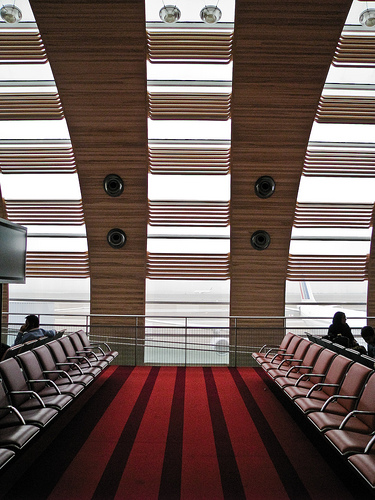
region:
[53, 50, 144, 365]
a large brown panel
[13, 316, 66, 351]
a man on a seat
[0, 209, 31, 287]
a TV over the man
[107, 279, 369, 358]
a plane out the window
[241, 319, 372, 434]
a row of empty chairs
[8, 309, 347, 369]
a fence behind the chairs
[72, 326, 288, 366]
a ramp behind the fence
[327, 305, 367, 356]
a woman on a chair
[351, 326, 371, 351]
a man bending over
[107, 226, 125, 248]
a brown circle on the panel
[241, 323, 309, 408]
chairs at the airport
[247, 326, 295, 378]
chairs at the airport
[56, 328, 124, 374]
chairs at the airport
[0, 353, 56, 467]
chairs at the airport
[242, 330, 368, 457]
chairs at the airport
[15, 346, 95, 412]
chairs at the airport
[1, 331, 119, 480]
chairs at the airport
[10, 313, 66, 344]
a man waiting for his plane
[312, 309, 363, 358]
a woman waiting for her plane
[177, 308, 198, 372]
This is a pole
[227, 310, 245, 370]
This is a pole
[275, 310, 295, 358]
This is a pole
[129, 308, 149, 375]
This is a pole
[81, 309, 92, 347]
This is a pole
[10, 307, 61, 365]
This is a person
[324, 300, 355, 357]
This is a person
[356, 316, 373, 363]
This is a person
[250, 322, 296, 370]
This is a seat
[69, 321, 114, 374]
This is a seat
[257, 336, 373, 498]
ROW OF RED SEATS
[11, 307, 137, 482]
ROW OF RED SEATS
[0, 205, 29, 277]
TV ABOVE ROW OF SEATS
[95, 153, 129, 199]
BLACK ROUND OBJECT ON WOOD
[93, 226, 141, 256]
BLACK ROUND OBJECT ON WOOD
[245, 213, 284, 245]
BLACK ROUND OBJECT ON WOOD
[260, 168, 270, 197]
BLACK ROUND OBJECT ON WOOD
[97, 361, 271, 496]
RED CARPET ON FLOOR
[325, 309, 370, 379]
PERSON SITTING ON THE RIGHT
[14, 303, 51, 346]
PERSON SITTING ON THE LEFT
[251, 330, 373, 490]
Row of red seats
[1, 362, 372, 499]
Red carpet with dark red stripes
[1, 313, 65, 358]
Man talking on his cellphone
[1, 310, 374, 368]
Metal netted railing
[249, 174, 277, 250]
Two black circles on the wall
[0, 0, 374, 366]
Large wood and glass wall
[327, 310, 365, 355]
Woman sitting on a chair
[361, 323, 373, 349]
A person's head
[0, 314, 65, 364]
Man in a light blue dress shirt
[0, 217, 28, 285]
Silver flat screen television